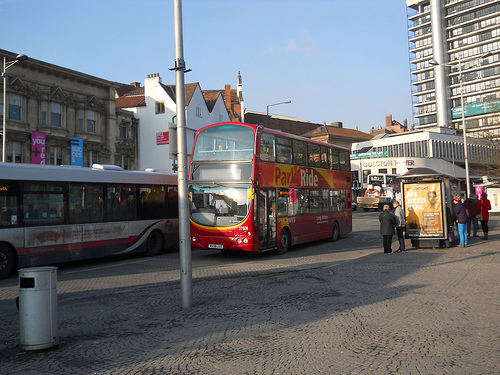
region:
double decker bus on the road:
[182, 94, 375, 262]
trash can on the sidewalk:
[3, 267, 84, 349]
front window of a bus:
[196, 183, 257, 233]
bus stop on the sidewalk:
[393, 165, 495, 256]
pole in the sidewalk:
[161, 5, 222, 317]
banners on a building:
[29, 128, 96, 163]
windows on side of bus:
[0, 183, 192, 215]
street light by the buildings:
[261, 96, 299, 118]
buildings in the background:
[395, 0, 498, 158]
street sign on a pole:
[150, 124, 172, 154]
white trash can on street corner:
[7, 260, 75, 351]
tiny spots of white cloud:
[248, 31, 340, 51]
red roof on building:
[110, 84, 152, 109]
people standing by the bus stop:
[374, 195, 417, 250]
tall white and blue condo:
[393, 6, 483, 133]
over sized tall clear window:
[178, 123, 263, 239]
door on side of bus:
[247, 186, 288, 256]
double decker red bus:
[190, 119, 362, 257]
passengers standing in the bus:
[61, 178, 151, 227]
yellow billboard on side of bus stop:
[391, 173, 451, 247]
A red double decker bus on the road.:
[182, 119, 354, 259]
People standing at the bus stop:
[366, 190, 477, 257]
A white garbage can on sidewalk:
[16, 260, 80, 357]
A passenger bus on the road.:
[16, 165, 181, 266]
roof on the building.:
[158, 71, 241, 109]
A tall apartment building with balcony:
[408, 13, 490, 147]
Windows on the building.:
[14, 91, 108, 131]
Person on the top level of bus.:
[209, 139, 231, 160]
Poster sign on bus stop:
[403, 180, 443, 245]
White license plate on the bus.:
[202, 238, 224, 251]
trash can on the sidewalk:
[13, 266, 67, 349]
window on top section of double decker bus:
[191, 124, 253, 176]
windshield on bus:
[189, 186, 251, 228]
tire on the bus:
[281, 232, 290, 252]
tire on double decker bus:
[330, 222, 342, 243]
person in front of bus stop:
[373, 200, 394, 256]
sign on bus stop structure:
[403, 180, 448, 239]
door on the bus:
[258, 192, 279, 248]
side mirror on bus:
[249, 188, 253, 201]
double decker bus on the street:
[190, 124, 351, 253]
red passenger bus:
[193, 98, 351, 263]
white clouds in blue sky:
[13, 7, 35, 47]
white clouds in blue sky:
[19, 13, 57, 50]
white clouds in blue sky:
[56, 5, 80, 65]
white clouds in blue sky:
[93, 10, 108, 57]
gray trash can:
[9, 261, 61, 352]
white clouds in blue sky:
[209, 21, 247, 72]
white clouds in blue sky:
[260, 23, 275, 78]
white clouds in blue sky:
[266, 37, 301, 79]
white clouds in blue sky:
[310, 38, 364, 106]